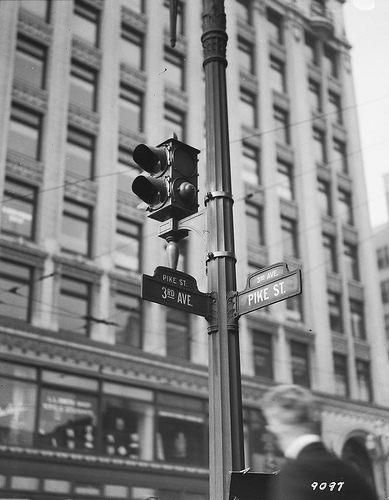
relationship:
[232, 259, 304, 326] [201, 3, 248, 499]
two street signs located on street post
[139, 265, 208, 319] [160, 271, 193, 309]
street sign says pike st 3rd ave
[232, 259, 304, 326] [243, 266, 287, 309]
two street signs on other side says 3rd ave pike street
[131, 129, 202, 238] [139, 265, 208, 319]
street light on top of street sign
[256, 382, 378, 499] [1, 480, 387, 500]
man waits to cross street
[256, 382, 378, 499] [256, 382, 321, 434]
man has grey hair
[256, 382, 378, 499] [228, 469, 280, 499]
man has a briefcase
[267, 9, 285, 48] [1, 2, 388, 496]
window on high rise building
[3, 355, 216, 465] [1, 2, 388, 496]
store front on nd level of building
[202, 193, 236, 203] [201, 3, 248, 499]
metal ring around post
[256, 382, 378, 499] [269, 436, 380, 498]
man in a suit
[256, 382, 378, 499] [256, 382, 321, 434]
man has short hair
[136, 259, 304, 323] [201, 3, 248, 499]
two street signs on post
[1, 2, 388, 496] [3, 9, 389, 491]
building has many windows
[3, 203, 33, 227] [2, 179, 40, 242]
words in window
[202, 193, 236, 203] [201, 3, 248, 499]
metal ring midway on post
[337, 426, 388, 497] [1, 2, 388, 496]
entrance to city building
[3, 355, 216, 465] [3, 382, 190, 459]
store front has displays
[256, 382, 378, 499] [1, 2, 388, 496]
man in front of highrise building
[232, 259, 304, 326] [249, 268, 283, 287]
two street signs for 3rd ave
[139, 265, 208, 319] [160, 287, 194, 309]
street sign also for 3rd ave